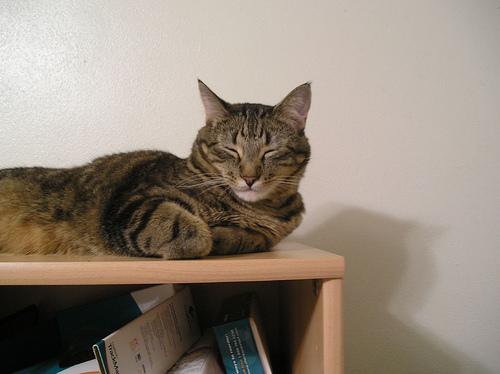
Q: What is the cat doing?
A: Sleeping.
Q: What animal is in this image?
A: Cat.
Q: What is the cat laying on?
A: Bookshelf.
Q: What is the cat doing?
A: Sleeping.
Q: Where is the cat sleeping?
A: Bookshelf.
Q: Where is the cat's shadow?
A: On wall.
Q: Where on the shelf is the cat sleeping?
A: Top.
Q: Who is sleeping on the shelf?
A: Cat.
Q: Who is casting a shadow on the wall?
A: Cat.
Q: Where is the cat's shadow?
A: On wall.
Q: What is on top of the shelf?
A: Cat.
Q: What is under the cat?
A: Wooden shelf.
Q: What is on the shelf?
A: Gray tabby cat.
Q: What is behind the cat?
A: Beige wall.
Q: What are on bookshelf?
A: Books.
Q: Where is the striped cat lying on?
A: Bookcase.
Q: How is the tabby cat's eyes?
A: Closed.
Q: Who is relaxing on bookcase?
A: A cat.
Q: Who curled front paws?
A: Striped cat.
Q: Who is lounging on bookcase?
A: Contented cat.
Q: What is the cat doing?
A: Sleeping on shelf.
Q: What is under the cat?
A: Bookshelf.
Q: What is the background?
A: White wall.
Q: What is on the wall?
A: Shadow of cat.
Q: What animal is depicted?
A: Cat.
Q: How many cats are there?
A: 1.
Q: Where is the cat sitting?
A: A bookshelf.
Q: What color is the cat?
A: Gray.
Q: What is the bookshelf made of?
A: Wood.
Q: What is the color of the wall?
A: White.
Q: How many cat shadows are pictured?
A: 1.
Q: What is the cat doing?
A: Sleeping.